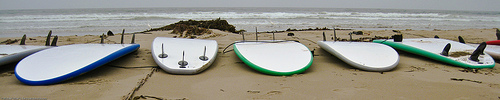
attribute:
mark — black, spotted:
[177, 54, 190, 70]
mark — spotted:
[157, 50, 170, 60]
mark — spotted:
[198, 53, 212, 64]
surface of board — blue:
[13, 41, 139, 88]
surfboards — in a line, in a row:
[3, 34, 499, 86]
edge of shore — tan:
[1, 34, 498, 100]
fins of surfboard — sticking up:
[440, 39, 489, 61]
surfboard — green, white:
[233, 39, 312, 79]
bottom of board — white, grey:
[152, 34, 220, 72]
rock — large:
[147, 17, 241, 37]